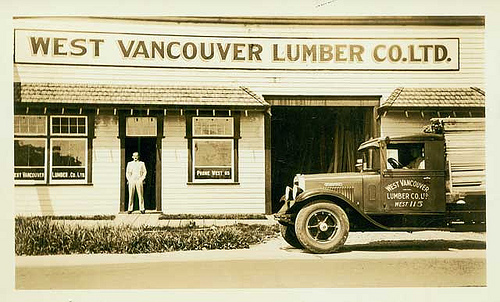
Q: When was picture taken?
A: Daytime.